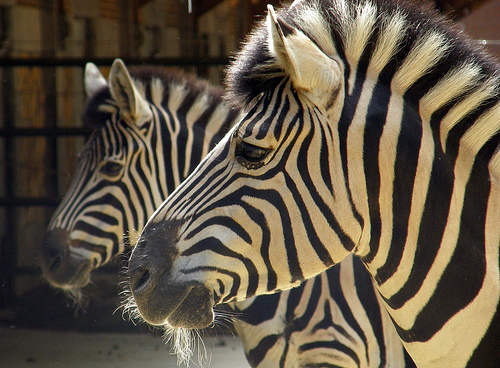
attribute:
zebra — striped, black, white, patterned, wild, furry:
[129, 0, 499, 366]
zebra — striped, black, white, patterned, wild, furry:
[40, 56, 416, 368]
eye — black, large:
[236, 142, 269, 161]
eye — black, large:
[102, 160, 122, 173]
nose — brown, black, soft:
[128, 220, 181, 320]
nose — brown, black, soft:
[40, 229, 72, 287]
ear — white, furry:
[263, 1, 341, 109]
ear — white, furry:
[83, 60, 107, 101]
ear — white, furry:
[108, 57, 150, 125]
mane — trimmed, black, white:
[223, 0, 499, 178]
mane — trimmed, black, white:
[79, 63, 245, 132]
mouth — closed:
[148, 277, 217, 332]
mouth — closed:
[59, 258, 94, 293]